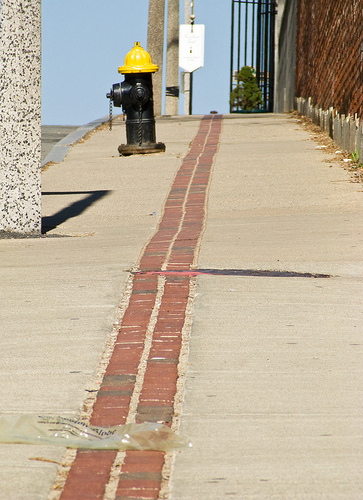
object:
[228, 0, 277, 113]
fence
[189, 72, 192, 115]
pole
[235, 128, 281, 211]
ground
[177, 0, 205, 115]
poles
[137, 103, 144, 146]
chains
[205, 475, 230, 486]
gum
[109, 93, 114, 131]
chain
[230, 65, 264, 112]
green bush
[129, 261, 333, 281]
manhole cover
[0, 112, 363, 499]
sidewalk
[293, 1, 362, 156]
wall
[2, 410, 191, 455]
paper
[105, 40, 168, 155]
hydrant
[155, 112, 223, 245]
bricks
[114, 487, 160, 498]
brick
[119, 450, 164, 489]
brick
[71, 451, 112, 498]
brick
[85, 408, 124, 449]
brick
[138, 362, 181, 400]
brick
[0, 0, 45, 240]
poles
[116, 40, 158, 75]
top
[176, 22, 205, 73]
sign